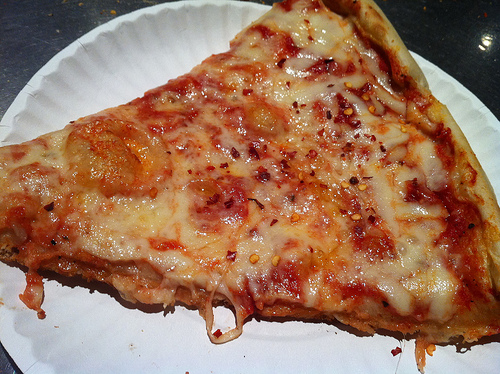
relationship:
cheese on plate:
[0, 1, 499, 374] [2, 1, 500, 373]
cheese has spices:
[0, 1, 499, 374] [344, 108, 353, 115]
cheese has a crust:
[0, 1, 499, 374] [321, 1, 499, 334]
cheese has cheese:
[0, 1, 499, 374] [1, 2, 471, 343]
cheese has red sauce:
[0, 1, 499, 374] [255, 3, 484, 314]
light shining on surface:
[479, 33, 492, 53] [2, 2, 499, 373]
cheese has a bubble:
[1, 2, 471, 343] [71, 120, 173, 196]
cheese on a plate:
[0, 1, 499, 374] [2, 1, 500, 373]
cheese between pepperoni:
[1, 2, 471, 343] [193, 187, 247, 230]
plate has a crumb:
[2, 1, 500, 373] [391, 348, 402, 355]